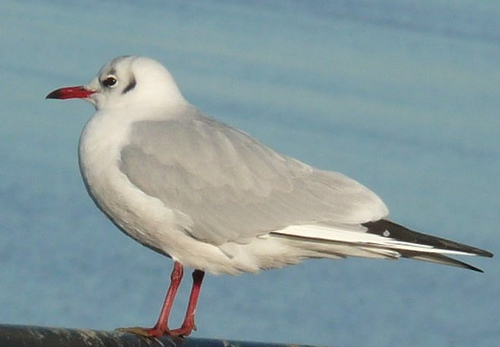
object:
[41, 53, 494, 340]
bird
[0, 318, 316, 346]
rail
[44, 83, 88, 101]
beak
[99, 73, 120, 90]
eye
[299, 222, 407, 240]
feather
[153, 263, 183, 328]
leg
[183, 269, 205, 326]
legs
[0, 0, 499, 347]
sky